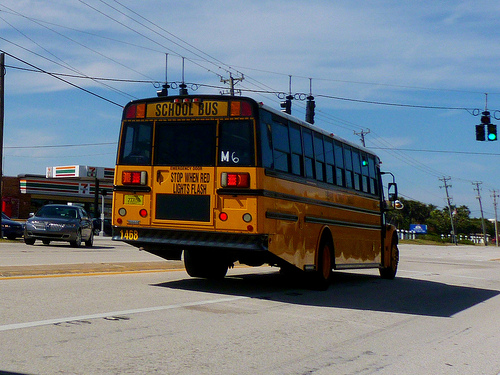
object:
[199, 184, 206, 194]
writing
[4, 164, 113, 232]
building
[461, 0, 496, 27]
clouds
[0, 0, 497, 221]
sky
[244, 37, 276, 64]
clouds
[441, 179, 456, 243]
poles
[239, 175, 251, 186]
tail light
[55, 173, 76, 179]
red stripe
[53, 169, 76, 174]
green stripe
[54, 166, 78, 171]
orange stripe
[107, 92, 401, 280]
bus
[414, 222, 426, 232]
sign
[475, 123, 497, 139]
green light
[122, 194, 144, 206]
license plate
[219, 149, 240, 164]
m6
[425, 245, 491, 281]
road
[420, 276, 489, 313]
road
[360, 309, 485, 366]
road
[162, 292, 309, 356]
road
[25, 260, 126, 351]
road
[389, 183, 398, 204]
mirror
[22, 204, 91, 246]
car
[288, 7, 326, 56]
white clouds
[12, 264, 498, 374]
lane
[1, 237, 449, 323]
lane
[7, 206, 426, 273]
lane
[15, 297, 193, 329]
white line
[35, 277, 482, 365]
road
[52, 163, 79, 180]
sign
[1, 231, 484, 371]
street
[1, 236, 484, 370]
road